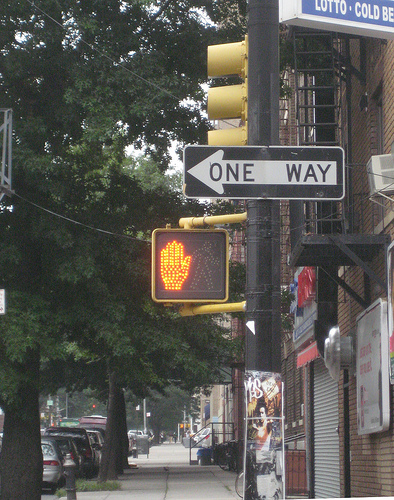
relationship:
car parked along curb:
[44, 426, 92, 495] [42, 438, 157, 498]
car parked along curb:
[45, 426, 93, 477] [42, 438, 157, 498]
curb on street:
[42, 438, 157, 498] [1, 410, 180, 495]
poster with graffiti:
[244, 370, 286, 498] [240, 375, 270, 415]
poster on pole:
[244, 370, 286, 498] [238, 199, 288, 499]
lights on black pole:
[204, 30, 250, 149] [241, 0, 283, 499]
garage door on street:
[282, 318, 343, 499] [8, 418, 198, 495]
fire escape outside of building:
[289, 34, 393, 308] [235, 6, 387, 497]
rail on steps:
[188, 418, 235, 464] [182, 410, 235, 467]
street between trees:
[8, 418, 293, 500] [1, 0, 239, 499]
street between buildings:
[8, 418, 293, 500] [190, 3, 393, 496]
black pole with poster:
[241, 0, 283, 499] [244, 370, 286, 498]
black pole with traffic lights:
[241, 0, 283, 499] [148, 224, 228, 303]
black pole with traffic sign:
[241, 0, 283, 499] [182, 146, 345, 198]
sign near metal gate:
[358, 296, 390, 436] [313, 353, 338, 498]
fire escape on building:
[289, 34, 367, 295] [295, 277, 380, 486]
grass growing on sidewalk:
[79, 478, 91, 493] [122, 445, 206, 493]